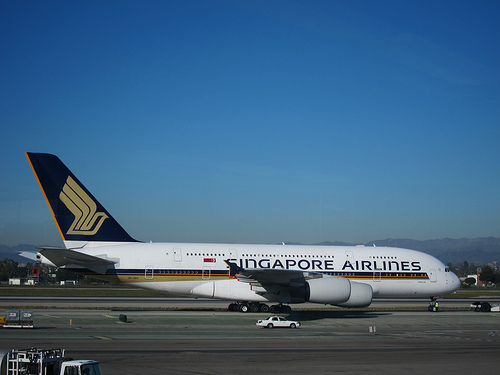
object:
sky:
[2, 1, 500, 232]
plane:
[19, 151, 460, 315]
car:
[256, 317, 301, 330]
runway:
[2, 313, 500, 371]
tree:
[476, 264, 499, 287]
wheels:
[227, 300, 249, 312]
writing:
[408, 256, 423, 271]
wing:
[225, 262, 324, 299]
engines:
[311, 278, 353, 305]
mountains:
[402, 222, 500, 255]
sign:
[203, 256, 217, 263]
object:
[368, 327, 378, 335]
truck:
[2, 346, 100, 375]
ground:
[1, 318, 499, 374]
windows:
[391, 253, 401, 260]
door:
[200, 263, 211, 281]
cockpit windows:
[443, 266, 453, 274]